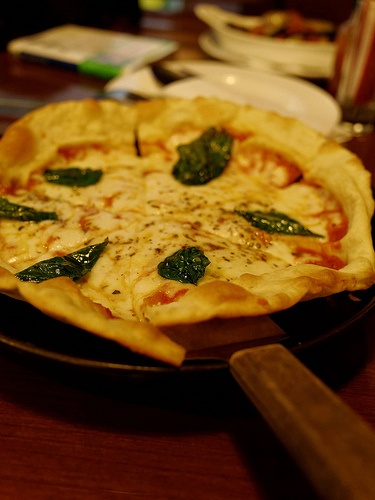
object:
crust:
[117, 322, 185, 367]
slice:
[133, 94, 341, 217]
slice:
[1, 97, 147, 222]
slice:
[171, 140, 374, 284]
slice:
[0, 217, 186, 367]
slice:
[129, 213, 354, 329]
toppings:
[1, 124, 327, 288]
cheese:
[79, 189, 141, 237]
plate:
[155, 68, 342, 137]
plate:
[193, 4, 336, 77]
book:
[6, 21, 180, 78]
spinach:
[172, 125, 235, 187]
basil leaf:
[235, 211, 327, 237]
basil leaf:
[14, 235, 110, 283]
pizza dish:
[0, 286, 375, 404]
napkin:
[102, 65, 160, 97]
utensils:
[149, 62, 199, 85]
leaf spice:
[41, 166, 103, 188]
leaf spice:
[0, 196, 59, 223]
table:
[0, 0, 375, 499]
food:
[225, 8, 337, 40]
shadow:
[0, 347, 375, 499]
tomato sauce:
[296, 247, 349, 269]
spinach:
[157, 244, 211, 286]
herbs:
[0, 127, 325, 287]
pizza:
[0, 92, 374, 367]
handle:
[229, 343, 375, 499]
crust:
[261, 116, 304, 149]